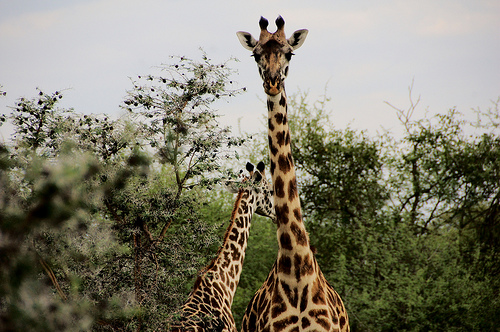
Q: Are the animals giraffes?
A: Yes, all the animals are giraffes.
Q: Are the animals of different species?
A: No, all the animals are giraffes.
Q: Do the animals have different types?
A: No, all the animals are giraffes.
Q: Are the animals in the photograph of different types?
A: No, all the animals are giraffes.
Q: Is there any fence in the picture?
A: No, there are no fences.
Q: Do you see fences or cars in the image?
A: No, there are no fences or cars.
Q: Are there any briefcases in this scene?
A: No, there are no briefcases.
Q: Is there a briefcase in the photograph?
A: No, there are no briefcases.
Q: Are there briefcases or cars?
A: No, there are no briefcases or cars.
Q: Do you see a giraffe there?
A: Yes, there is a giraffe.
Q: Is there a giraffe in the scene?
A: Yes, there is a giraffe.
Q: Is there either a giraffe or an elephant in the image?
A: Yes, there is a giraffe.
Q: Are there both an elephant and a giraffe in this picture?
A: No, there is a giraffe but no elephants.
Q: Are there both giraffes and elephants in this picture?
A: No, there is a giraffe but no elephants.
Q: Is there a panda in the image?
A: No, there are no pandas.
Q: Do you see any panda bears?
A: No, there are no panda bears.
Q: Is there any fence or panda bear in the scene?
A: No, there are no pandas or fences.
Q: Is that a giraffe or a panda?
A: That is a giraffe.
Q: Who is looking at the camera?
A: The giraffe is looking at the camera.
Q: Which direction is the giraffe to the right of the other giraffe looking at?
A: The giraffe is looking at the camera.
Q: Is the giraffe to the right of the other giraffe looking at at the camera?
A: Yes, the giraffe is looking at the camera.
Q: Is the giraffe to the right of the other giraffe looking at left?
A: No, the giraffe is looking at the camera.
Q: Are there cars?
A: No, there are no cars.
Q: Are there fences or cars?
A: No, there are no cars or fences.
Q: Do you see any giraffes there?
A: Yes, there is a giraffe.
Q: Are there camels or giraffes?
A: Yes, there is a giraffe.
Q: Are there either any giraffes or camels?
A: Yes, there is a giraffe.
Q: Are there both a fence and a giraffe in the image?
A: No, there is a giraffe but no fences.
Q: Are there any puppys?
A: No, there are no puppys.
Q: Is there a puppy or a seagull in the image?
A: No, there are no puppys or seagulls.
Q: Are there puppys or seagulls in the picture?
A: No, there are no puppys or seagulls.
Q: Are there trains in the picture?
A: No, there are no trains.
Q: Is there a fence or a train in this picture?
A: No, there are no trains or fences.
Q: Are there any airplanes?
A: No, there are no airplanes.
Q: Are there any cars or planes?
A: No, there are no planes or cars.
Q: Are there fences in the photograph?
A: No, there are no fences.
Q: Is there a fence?
A: No, there are no fences.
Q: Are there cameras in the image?
A: Yes, there is a camera.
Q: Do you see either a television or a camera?
A: Yes, there is a camera.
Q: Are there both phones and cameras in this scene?
A: No, there is a camera but no phones.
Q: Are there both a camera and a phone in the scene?
A: No, there is a camera but no phones.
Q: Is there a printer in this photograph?
A: No, there are no printers.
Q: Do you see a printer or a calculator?
A: No, there are no printers or calculators.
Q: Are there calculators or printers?
A: No, there are no printers or calculators.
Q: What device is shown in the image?
A: The device is a camera.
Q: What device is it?
A: The device is a camera.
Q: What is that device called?
A: This is a camera.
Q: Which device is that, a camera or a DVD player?
A: This is a camera.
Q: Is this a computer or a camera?
A: This is a camera.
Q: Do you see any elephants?
A: No, there are no elephants.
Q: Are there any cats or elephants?
A: No, there are no elephants or cats.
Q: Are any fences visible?
A: No, there are no fences.